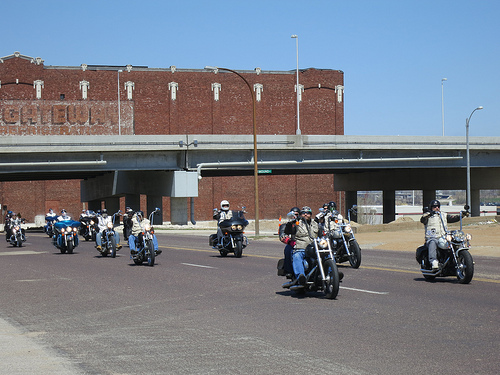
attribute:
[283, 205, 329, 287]
person — riding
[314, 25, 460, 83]
sky — blue 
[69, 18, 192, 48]
clouds — white 